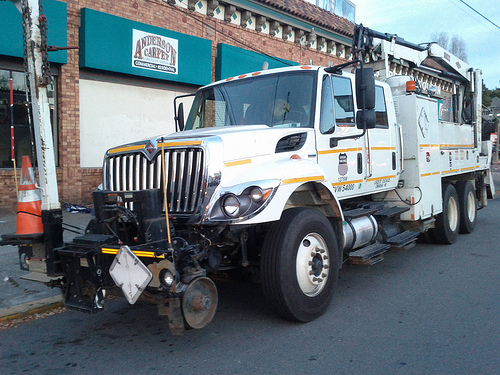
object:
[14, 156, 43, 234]
cone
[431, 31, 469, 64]
tree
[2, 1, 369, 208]
facade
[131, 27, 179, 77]
sign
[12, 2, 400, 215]
business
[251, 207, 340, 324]
tire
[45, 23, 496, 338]
truck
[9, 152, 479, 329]
curb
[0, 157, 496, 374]
road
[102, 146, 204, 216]
grill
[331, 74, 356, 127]
window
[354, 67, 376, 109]
mirror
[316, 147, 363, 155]
stripes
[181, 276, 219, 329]
wheels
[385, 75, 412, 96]
bucket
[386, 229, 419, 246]
steps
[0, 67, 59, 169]
window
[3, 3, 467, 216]
store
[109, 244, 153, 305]
diamond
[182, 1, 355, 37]
cornice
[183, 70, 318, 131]
windshield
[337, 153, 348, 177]
emblem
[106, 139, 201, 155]
stripe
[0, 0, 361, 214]
bricks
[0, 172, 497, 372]
street